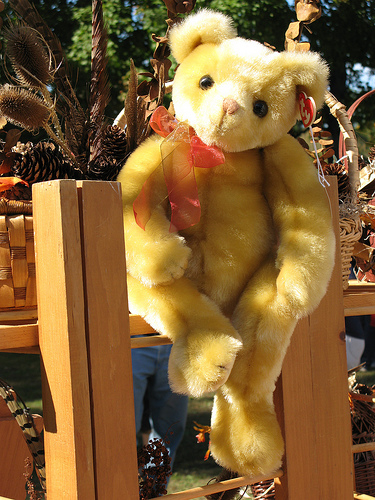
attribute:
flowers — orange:
[0, 168, 28, 201]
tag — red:
[295, 86, 319, 129]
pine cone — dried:
[7, 139, 79, 181]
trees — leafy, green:
[2, 3, 374, 159]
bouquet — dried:
[8, 3, 169, 171]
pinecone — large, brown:
[10, 139, 66, 177]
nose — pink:
[202, 85, 238, 137]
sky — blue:
[351, 68, 367, 87]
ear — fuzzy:
[283, 44, 331, 121]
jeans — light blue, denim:
[129, 346, 187, 493]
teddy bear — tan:
[170, 39, 308, 209]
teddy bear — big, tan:
[118, 9, 337, 477]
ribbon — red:
[131, 104, 225, 232]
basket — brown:
[199, 56, 373, 338]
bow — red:
[139, 140, 231, 211]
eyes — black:
[196, 72, 273, 117]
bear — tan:
[111, 10, 330, 479]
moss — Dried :
[336, 177, 359, 220]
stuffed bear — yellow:
[116, 10, 332, 476]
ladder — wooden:
[30, 171, 139, 494]